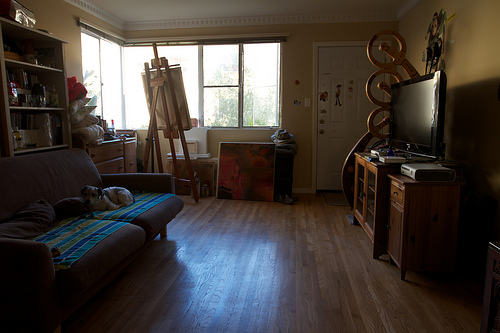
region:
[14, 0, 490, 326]
the photo was in a living room.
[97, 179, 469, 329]
The floor is made of wood.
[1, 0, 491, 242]
The walls are yellow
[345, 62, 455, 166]
TV on a stand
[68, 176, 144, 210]
Dog on a couch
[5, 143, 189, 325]
The couch is tan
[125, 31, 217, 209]
Art easel in the room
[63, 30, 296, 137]
Sunlight coming in the windows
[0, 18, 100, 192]
Bookshelf by the wall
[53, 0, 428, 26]
The ceiling is white.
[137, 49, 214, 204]
the easel beside the window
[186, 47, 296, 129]
the window is bare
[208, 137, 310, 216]
the painting on the floor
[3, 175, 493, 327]
the floor is wooden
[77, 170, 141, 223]
the dog on the sofa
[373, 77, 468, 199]
the television on the tv stand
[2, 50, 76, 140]
the shelves behind the sofa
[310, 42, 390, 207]
the door is closed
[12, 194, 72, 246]
the pillow on the sofa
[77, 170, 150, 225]
the dog is black and white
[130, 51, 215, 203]
the easel is made of wood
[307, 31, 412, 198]
the door is white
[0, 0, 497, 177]
the wall is yellow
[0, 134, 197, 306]
the couch is brown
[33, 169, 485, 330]
the floor is made of wood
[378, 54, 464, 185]
the tv is black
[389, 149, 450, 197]
white game console next to tv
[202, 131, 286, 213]
painting on the floor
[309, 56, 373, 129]
stickers are on door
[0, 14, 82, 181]
shelf behind the couch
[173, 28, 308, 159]
The trees are outside the window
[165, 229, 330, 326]
The floor is wooden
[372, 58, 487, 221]
The tv is flat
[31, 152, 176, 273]
The dog is on the couch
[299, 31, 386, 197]
The door is shut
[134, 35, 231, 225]
the window is letting sun in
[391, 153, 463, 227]
The Xbox is on a cabinet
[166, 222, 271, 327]
The sun is hitting the floor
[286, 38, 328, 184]
The walls are light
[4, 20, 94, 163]
The book shelf is behind the couch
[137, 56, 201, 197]
a wooden art easel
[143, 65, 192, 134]
a very large canvas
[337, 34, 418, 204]
a large wooden sculpture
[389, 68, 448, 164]
a flat screen tv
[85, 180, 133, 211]
an animal on the couch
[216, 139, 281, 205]
a painting against the wall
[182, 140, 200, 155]
a blank canvas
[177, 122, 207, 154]
a blank canvas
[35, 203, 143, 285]
a multi colored seat cushion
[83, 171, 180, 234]
a multi colored seat cushion